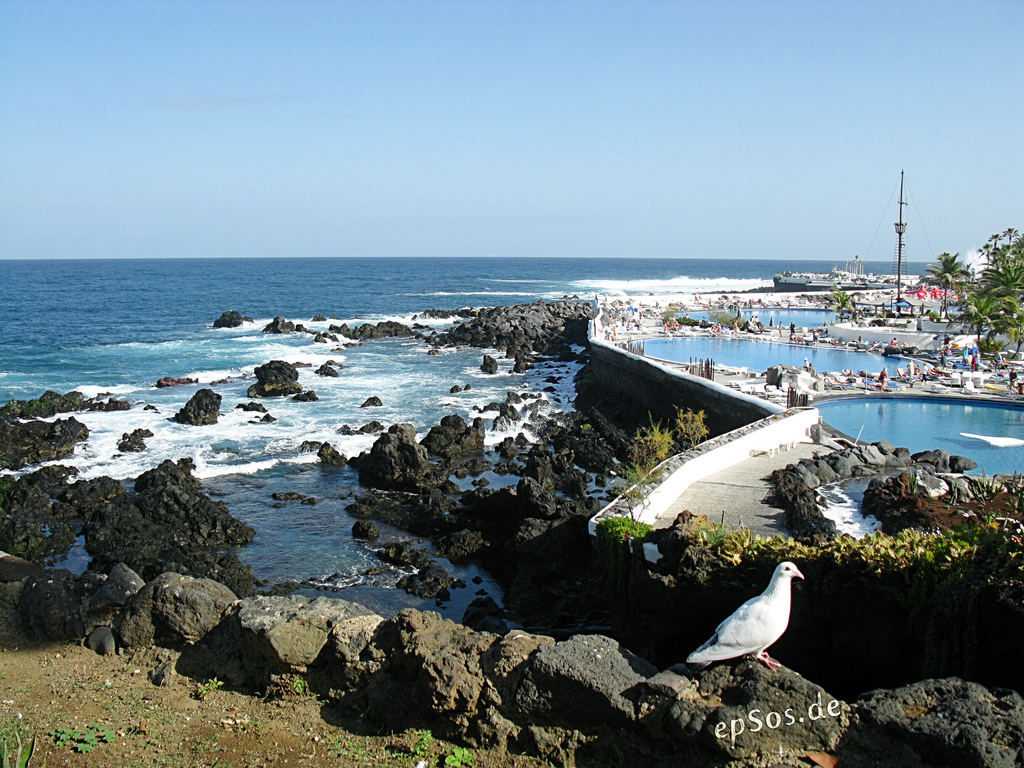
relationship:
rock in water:
[338, 504, 378, 544] [211, 443, 488, 616]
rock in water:
[347, 417, 447, 504] [221, 426, 587, 643]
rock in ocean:
[419, 406, 484, 471] [5, 255, 939, 625]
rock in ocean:
[331, 320, 440, 346] [18, 247, 507, 314]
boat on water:
[757, 269, 915, 282] [12, 249, 950, 394]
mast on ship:
[891, 165, 917, 278] [766, 264, 944, 293]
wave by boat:
[565, 262, 782, 291] [759, 247, 913, 293]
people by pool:
[804, 361, 1023, 400] [636, 327, 911, 382]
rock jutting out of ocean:
[243, 355, 304, 401] [5, 255, 939, 625]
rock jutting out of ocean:
[214, 307, 254, 329] [5, 255, 939, 625]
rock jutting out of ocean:
[256, 314, 300, 338] [5, 255, 939, 625]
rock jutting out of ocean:
[361, 392, 387, 410] [5, 255, 939, 625]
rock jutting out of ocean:
[353, 422, 464, 498] [5, 255, 939, 625]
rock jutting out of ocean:
[214, 307, 243, 329] [5, 255, 939, 625]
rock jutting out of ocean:
[3, 417, 88, 472] [5, 255, 939, 625]